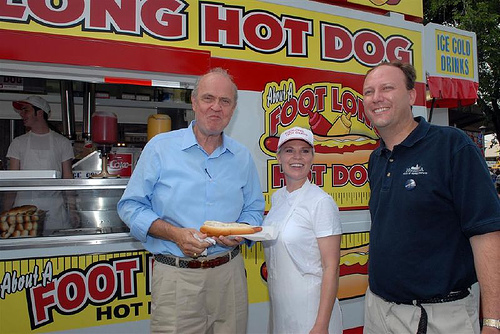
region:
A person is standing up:
[115, 62, 272, 330]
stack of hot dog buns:
[0, 203, 40, 241]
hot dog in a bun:
[194, 206, 272, 246]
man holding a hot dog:
[126, 67, 276, 263]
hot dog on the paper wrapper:
[198, 213, 279, 246]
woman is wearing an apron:
[259, 179, 345, 332]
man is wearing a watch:
[478, 314, 498, 331]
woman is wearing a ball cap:
[276, 127, 318, 185]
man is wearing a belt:
[153, 243, 244, 276]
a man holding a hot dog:
[116, 65, 264, 332]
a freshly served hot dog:
[201, 220, 266, 240]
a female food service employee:
[261, 124, 343, 332]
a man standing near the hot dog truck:
[361, 60, 499, 331]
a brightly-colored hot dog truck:
[0, 0, 480, 332]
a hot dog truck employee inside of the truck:
[4, 93, 79, 235]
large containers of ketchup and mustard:
[89, 107, 171, 177]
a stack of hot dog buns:
[0, 203, 42, 238]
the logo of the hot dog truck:
[260, 72, 375, 208]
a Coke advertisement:
[106, 152, 133, 175]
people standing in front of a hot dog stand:
[0, 0, 477, 331]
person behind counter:
[0, 80, 90, 240]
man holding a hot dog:
[160, 70, 266, 251]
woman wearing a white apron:
[265, 130, 340, 331]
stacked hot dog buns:
[0, 196, 50, 242]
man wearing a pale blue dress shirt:
[120, 67, 261, 254]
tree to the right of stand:
[410, 0, 496, 148]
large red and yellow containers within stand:
[80, 97, 172, 152]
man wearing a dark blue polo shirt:
[361, 58, 494, 298]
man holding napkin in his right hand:
[175, 220, 218, 268]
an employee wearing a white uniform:
[256, 119, 342, 329]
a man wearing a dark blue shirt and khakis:
[347, 58, 495, 330]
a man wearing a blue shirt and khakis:
[121, 66, 268, 330]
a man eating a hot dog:
[115, 64, 267, 333]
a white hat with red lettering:
[269, 124, 322, 154]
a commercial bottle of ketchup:
[84, 106, 117, 149]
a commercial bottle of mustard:
[141, 111, 172, 148]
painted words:
[0, 255, 148, 329]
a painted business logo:
[251, 72, 388, 212]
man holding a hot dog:
[192, 206, 279, 251]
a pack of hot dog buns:
[2, 203, 57, 240]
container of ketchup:
[86, 113, 121, 154]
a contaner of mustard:
[136, 110, 171, 137]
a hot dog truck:
[4, 7, 467, 247]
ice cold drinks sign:
[432, 20, 493, 101]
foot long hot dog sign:
[252, 74, 378, 216]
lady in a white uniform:
[263, 127, 343, 308]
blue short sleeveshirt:
[340, 108, 496, 325]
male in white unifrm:
[7, 99, 93, 216]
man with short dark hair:
[351, 38, 466, 320]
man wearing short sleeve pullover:
[360, 111, 492, 333]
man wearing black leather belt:
[343, 273, 489, 331]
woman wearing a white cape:
[232, 89, 343, 331]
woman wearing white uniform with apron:
[225, 156, 380, 329]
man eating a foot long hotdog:
[100, 53, 278, 274]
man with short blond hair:
[137, 35, 267, 150]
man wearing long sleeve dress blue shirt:
[104, 58, 268, 285]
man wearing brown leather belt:
[129, 212, 270, 294]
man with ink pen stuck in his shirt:
[118, 71, 266, 291]